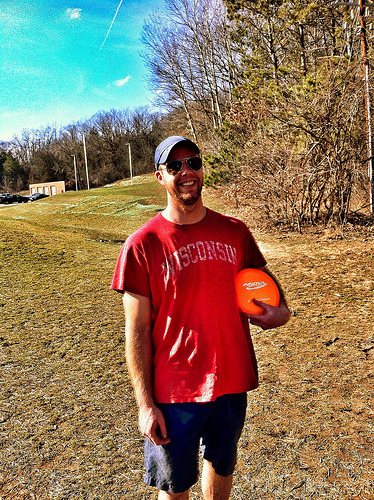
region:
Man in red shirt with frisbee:
[111, 136, 290, 498]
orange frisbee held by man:
[235, 269, 278, 314]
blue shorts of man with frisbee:
[141, 389, 246, 492]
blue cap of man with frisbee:
[153, 134, 200, 163]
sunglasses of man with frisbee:
[160, 158, 204, 175]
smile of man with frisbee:
[166, 168, 206, 201]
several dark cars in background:
[1, 189, 45, 205]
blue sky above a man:
[1, 1, 239, 143]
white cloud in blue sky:
[115, 73, 133, 89]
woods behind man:
[138, 0, 372, 231]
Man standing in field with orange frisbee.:
[98, 122, 288, 499]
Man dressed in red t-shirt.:
[102, 201, 302, 406]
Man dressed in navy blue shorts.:
[125, 385, 282, 489]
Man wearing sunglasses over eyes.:
[152, 152, 208, 177]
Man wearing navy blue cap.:
[140, 131, 211, 163]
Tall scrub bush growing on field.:
[204, 43, 372, 237]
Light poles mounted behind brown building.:
[64, 121, 148, 194]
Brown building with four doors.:
[23, 179, 73, 198]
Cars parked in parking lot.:
[1, 187, 54, 208]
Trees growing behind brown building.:
[29, 102, 156, 191]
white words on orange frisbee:
[237, 278, 277, 292]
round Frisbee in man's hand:
[212, 257, 279, 330]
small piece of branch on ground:
[320, 326, 347, 354]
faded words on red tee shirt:
[165, 233, 259, 274]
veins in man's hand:
[121, 398, 161, 445]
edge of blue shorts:
[136, 467, 209, 499]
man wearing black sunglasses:
[150, 147, 230, 176]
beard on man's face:
[153, 182, 230, 204]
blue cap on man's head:
[132, 117, 218, 177]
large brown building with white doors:
[24, 173, 91, 208]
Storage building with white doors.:
[14, 169, 71, 197]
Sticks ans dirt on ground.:
[257, 385, 370, 486]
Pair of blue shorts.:
[136, 393, 250, 492]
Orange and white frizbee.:
[223, 253, 288, 334]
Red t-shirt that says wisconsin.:
[90, 215, 258, 430]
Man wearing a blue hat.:
[132, 116, 207, 180]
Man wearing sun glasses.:
[105, 156, 228, 198]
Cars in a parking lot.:
[0, 187, 45, 205]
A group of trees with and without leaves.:
[145, 6, 367, 207]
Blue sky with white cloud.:
[28, 9, 109, 38]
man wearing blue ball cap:
[135, 128, 224, 226]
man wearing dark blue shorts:
[133, 376, 261, 494]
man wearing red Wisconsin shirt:
[98, 212, 291, 427]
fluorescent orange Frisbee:
[234, 267, 279, 338]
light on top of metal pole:
[63, 147, 85, 197]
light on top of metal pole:
[77, 126, 101, 194]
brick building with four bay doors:
[25, 180, 69, 203]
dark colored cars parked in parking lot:
[2, 184, 55, 214]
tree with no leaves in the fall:
[240, 74, 373, 234]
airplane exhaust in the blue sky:
[87, 1, 141, 56]